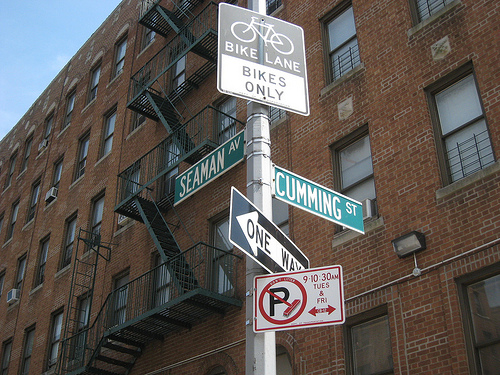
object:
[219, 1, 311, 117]
sign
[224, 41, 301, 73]
bike lane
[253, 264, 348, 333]
sign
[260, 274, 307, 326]
no parking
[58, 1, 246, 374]
fire escape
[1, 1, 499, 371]
building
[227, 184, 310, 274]
sign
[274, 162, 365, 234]
sign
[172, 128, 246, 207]
sign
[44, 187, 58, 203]
air conditioner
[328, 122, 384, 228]
window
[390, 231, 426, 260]
light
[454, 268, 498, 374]
windows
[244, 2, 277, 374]
pole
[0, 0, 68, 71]
sky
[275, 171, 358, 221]
cumming st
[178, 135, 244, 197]
seaman av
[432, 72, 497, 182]
window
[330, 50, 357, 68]
bars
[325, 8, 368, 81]
window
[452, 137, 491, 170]
bars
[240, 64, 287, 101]
bikes only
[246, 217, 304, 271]
one way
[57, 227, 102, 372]
ladder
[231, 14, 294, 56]
bike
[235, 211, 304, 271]
arrow